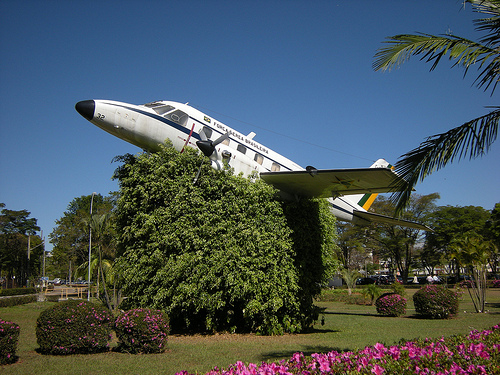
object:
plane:
[73, 97, 431, 234]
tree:
[116, 135, 340, 336]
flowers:
[0, 318, 22, 366]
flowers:
[48, 312, 78, 328]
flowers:
[124, 309, 151, 330]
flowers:
[375, 290, 406, 316]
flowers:
[412, 282, 459, 318]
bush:
[0, 317, 19, 363]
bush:
[37, 299, 113, 355]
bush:
[114, 306, 170, 354]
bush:
[376, 290, 405, 316]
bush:
[413, 281, 463, 316]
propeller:
[194, 126, 232, 189]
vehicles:
[34, 275, 95, 288]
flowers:
[288, 354, 325, 368]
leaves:
[373, 3, 499, 236]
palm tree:
[372, 1, 499, 234]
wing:
[256, 162, 417, 199]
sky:
[3, 3, 497, 257]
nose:
[73, 98, 97, 120]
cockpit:
[141, 100, 189, 130]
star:
[328, 172, 357, 191]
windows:
[195, 125, 220, 142]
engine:
[195, 138, 257, 176]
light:
[303, 163, 318, 178]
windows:
[235, 141, 253, 155]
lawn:
[3, 280, 499, 366]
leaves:
[172, 183, 257, 282]